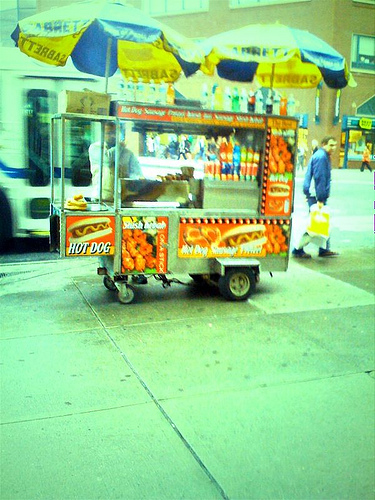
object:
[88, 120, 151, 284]
man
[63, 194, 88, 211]
hot dogs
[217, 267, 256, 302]
tire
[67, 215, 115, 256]
hot dog sign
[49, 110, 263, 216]
display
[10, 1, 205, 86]
sabrett umbrella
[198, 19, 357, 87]
sabrett umbrella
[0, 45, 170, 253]
commuter bus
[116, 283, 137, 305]
wheel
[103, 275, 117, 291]
wheel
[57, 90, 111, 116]
cardboard box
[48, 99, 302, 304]
cart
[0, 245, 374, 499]
sidewalk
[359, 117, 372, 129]
best buy sign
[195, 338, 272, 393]
spots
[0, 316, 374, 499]
ground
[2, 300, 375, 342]
lines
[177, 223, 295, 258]
picture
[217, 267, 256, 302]
wheels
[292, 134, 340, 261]
man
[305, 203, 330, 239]
bag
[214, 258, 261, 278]
cover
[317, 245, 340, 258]
sneakers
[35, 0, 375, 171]
building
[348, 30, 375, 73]
window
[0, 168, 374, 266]
street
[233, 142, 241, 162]
beverage bottles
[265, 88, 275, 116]
beverage bottles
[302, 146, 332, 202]
jacket